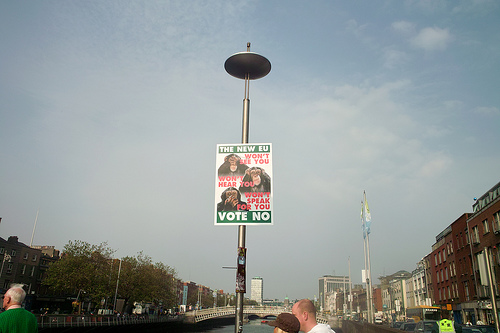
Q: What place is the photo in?
A: It is at the city.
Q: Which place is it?
A: It is a city.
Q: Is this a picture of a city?
A: Yes, it is showing a city.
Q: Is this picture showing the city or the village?
A: It is showing the city.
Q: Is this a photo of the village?
A: No, the picture is showing the city.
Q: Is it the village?
A: No, it is the city.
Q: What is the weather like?
A: It is clear.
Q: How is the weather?
A: It is clear.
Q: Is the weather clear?
A: Yes, it is clear.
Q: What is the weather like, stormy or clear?
A: It is clear.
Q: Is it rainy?
A: No, it is clear.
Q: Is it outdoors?
A: Yes, it is outdoors.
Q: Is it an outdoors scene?
A: Yes, it is outdoors.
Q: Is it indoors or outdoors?
A: It is outdoors.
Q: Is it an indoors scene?
A: No, it is outdoors.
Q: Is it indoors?
A: No, it is outdoors.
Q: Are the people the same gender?
A: No, they are both male and female.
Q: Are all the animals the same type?
A: Yes, all the animals are monkeys.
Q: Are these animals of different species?
A: No, all the animals are monkeys.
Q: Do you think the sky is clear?
A: Yes, the sky is clear.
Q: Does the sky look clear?
A: Yes, the sky is clear.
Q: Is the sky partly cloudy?
A: No, the sky is clear.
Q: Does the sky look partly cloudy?
A: No, the sky is clear.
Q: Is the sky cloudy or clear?
A: The sky is clear.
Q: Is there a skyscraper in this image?
A: Yes, there is a skyscraper.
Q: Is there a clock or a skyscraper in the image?
A: Yes, there is a skyscraper.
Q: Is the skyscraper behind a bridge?
A: Yes, the skyscraper is behind a bridge.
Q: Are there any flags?
A: Yes, there is a flag.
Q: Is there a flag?
A: Yes, there is a flag.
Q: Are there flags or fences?
A: Yes, there is a flag.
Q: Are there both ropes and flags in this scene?
A: No, there is a flag but no ropes.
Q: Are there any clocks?
A: No, there are no clocks.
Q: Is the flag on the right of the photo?
A: Yes, the flag is on the right of the image.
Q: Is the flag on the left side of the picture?
A: No, the flag is on the right of the image.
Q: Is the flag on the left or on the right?
A: The flag is on the right of the image.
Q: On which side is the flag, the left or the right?
A: The flag is on the right of the image.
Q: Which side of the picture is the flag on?
A: The flag is on the right of the image.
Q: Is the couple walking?
A: Yes, the couple is walking.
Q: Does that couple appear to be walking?
A: Yes, the couple is walking.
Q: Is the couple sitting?
A: No, the couple is walking.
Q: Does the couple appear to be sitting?
A: No, the couple is walking.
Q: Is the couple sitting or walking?
A: The couple is walking.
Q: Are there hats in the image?
A: Yes, there is a hat.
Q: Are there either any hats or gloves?
A: Yes, there is a hat.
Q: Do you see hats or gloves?
A: Yes, there is a hat.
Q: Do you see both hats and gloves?
A: No, there is a hat but no gloves.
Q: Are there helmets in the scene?
A: No, there are no helmets.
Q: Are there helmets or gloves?
A: No, there are no helmets or gloves.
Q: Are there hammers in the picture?
A: No, there are no hammers.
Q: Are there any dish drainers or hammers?
A: No, there are no hammers or dish drainers.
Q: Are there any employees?
A: No, there are no employees.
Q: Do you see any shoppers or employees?
A: No, there are no employees or shoppers.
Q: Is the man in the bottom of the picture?
A: Yes, the man is in the bottom of the image.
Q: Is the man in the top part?
A: No, the man is in the bottom of the image.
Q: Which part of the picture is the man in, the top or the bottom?
A: The man is in the bottom of the image.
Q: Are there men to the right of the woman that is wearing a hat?
A: Yes, there is a man to the right of the woman.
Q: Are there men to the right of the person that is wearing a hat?
A: Yes, there is a man to the right of the woman.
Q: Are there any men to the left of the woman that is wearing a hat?
A: No, the man is to the right of the woman.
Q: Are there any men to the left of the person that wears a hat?
A: No, the man is to the right of the woman.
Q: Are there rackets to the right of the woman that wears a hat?
A: No, there is a man to the right of the woman.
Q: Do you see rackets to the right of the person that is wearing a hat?
A: No, there is a man to the right of the woman.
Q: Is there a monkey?
A: Yes, there is a monkey.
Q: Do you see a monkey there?
A: Yes, there is a monkey.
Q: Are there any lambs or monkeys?
A: Yes, there is a monkey.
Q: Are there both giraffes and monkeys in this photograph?
A: No, there is a monkey but no giraffes.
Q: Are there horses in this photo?
A: No, there are no horses.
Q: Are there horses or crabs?
A: No, there are no horses or crabs.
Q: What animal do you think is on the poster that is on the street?
A: The monkey is on the poster.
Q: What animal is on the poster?
A: The monkey is on the poster.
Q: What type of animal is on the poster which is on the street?
A: The animal is a monkey.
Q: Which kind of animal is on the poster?
A: The animal is a monkey.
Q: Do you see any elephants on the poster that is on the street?
A: No, there is a monkey on the poster.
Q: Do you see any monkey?
A: Yes, there is a monkey.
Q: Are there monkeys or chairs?
A: Yes, there is a monkey.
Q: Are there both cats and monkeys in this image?
A: No, there is a monkey but no cats.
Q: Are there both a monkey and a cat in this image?
A: No, there is a monkey but no cats.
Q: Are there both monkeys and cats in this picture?
A: No, there is a monkey but no cats.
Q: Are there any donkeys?
A: No, there are no donkeys.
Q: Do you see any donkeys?
A: No, there are no donkeys.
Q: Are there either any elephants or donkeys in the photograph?
A: No, there are no donkeys or elephants.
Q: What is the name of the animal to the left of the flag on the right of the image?
A: The animal is a monkey.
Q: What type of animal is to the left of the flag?
A: The animal is a monkey.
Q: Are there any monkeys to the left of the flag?
A: Yes, there is a monkey to the left of the flag.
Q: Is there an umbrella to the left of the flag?
A: No, there is a monkey to the left of the flag.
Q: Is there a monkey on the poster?
A: Yes, there is a monkey on the poster.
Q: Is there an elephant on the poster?
A: No, there is a monkey on the poster.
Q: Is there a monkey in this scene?
A: Yes, there is a monkey.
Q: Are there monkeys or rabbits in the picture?
A: Yes, there is a monkey.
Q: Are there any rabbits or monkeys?
A: Yes, there is a monkey.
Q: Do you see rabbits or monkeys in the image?
A: Yes, there is a monkey.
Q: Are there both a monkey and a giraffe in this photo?
A: No, there is a monkey but no giraffes.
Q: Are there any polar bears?
A: No, there are no polar bears.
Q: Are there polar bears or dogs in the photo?
A: No, there are no polar bears or dogs.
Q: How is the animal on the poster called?
A: The animal is a monkey.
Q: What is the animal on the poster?
A: The animal is a monkey.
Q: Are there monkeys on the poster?
A: Yes, there is a monkey on the poster.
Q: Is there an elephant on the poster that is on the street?
A: No, there is a monkey on the poster.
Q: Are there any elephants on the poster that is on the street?
A: No, there is a monkey on the poster.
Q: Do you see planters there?
A: No, there are no planters.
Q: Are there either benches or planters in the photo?
A: No, there are no planters or benches.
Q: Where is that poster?
A: The poster is on the street.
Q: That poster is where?
A: The poster is on the street.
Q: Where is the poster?
A: The poster is on the street.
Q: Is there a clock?
A: No, there are no clocks.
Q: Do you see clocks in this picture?
A: No, there are no clocks.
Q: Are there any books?
A: No, there are no books.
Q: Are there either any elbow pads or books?
A: No, there are no books or elbow pads.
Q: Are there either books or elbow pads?
A: No, there are no books or elbow pads.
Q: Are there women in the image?
A: Yes, there is a woman.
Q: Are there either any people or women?
A: Yes, there is a woman.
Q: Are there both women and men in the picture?
A: Yes, there are both a woman and a man.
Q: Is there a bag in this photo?
A: No, there are no bags.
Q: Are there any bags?
A: No, there are no bags.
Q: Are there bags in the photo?
A: No, there are no bags.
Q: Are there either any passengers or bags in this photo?
A: No, there are no bags or passengers.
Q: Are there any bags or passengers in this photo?
A: No, there are no bags or passengers.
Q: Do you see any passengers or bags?
A: No, there are no bags or passengers.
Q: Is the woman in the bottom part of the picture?
A: Yes, the woman is in the bottom of the image.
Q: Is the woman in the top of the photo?
A: No, the woman is in the bottom of the image.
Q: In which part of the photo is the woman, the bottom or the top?
A: The woman is in the bottom of the image.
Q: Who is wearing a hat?
A: The woman is wearing a hat.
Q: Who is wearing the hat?
A: The woman is wearing a hat.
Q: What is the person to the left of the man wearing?
A: The woman is wearing a hat.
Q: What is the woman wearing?
A: The woman is wearing a hat.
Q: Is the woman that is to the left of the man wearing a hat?
A: Yes, the woman is wearing a hat.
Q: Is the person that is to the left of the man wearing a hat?
A: Yes, the woman is wearing a hat.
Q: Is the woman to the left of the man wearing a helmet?
A: No, the woman is wearing a hat.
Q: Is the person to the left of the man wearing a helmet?
A: No, the woman is wearing a hat.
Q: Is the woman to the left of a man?
A: Yes, the woman is to the left of a man.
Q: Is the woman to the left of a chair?
A: No, the woman is to the left of a man.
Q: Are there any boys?
A: No, there are no boys.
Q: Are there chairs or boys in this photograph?
A: No, there are no boys or chairs.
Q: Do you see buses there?
A: No, there are no buses.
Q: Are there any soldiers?
A: No, there are no soldiers.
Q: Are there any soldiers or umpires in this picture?
A: No, there are no soldiers or umpires.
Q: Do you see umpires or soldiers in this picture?
A: No, there are no soldiers or umpires.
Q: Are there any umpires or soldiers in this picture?
A: No, there are no soldiers or umpires.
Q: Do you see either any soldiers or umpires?
A: No, there are no soldiers or umpires.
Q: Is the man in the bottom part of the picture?
A: Yes, the man is in the bottom of the image.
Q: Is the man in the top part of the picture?
A: No, the man is in the bottom of the image.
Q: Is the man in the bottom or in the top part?
A: The man is in the bottom of the image.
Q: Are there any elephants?
A: No, there are no elephants.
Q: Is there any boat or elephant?
A: No, there are no elephants or boats.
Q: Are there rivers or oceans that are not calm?
A: No, there is a river but it is calm.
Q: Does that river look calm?
A: Yes, the river is calm.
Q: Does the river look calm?
A: Yes, the river is calm.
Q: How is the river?
A: The river is calm.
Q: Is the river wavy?
A: No, the river is calm.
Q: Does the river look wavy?
A: No, the river is calm.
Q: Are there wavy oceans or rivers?
A: No, there is a river but it is calm.